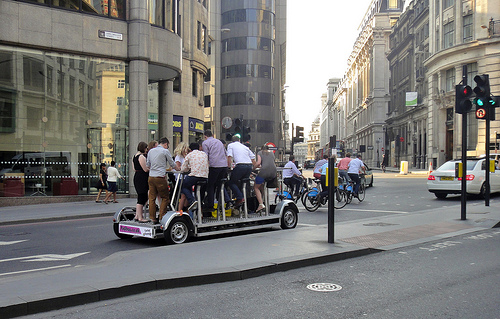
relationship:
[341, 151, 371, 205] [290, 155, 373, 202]
bunch of bikes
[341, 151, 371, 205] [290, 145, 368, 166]
bunch of bikers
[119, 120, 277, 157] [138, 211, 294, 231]
people on cart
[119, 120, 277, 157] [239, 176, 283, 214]
people on stools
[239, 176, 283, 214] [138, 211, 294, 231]
stools on cart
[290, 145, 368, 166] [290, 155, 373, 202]
bikers on bikes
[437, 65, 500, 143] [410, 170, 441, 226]
lights at intersection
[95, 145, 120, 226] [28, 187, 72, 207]
women on sidewalk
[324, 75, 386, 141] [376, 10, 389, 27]
building in back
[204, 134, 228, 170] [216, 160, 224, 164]
man in shirt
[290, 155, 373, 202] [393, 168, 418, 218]
bikes on street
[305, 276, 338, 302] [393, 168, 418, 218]
manhole on street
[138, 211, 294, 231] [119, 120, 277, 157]
cart with people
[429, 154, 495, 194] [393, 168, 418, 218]
car on street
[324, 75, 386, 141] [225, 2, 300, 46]
building has circular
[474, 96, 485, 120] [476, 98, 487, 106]
light showing green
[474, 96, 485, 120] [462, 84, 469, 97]
light showing red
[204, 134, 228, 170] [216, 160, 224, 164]
man wearing shirt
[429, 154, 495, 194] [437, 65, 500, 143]
car with lights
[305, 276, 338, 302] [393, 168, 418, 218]
manhole in street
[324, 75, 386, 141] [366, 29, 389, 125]
building with columns